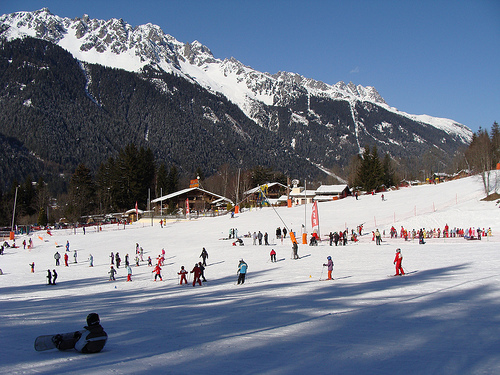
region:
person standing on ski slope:
[234, 261, 249, 282]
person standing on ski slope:
[324, 251, 343, 287]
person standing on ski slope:
[391, 243, 407, 285]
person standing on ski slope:
[264, 248, 278, 271]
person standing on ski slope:
[289, 238, 304, 259]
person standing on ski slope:
[56, 294, 100, 353]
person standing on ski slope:
[52, 249, 59, 268]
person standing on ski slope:
[70, 249, 82, 263]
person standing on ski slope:
[27, 237, 35, 244]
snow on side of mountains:
[87, 23, 244, 102]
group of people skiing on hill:
[33, 217, 484, 297]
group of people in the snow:
[78, 187, 433, 317]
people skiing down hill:
[107, 217, 453, 303]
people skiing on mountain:
[104, 202, 425, 309]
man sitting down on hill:
[23, 300, 113, 357]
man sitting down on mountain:
[28, 310, 113, 362]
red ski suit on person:
[390, 253, 405, 272]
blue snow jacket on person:
[238, 260, 250, 270]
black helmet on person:
[85, 312, 101, 327]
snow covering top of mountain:
[38, 8, 181, 80]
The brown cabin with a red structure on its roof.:
[151, 178, 234, 215]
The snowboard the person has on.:
[29, 335, 90, 350]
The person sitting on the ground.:
[36, 313, 111, 354]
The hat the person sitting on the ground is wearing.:
[87, 315, 104, 320]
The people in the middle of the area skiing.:
[27, 240, 433, 303]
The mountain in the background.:
[0, 4, 483, 192]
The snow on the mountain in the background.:
[2, 15, 479, 154]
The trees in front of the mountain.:
[7, 158, 277, 213]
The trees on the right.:
[348, 126, 498, 183]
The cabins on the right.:
[402, 162, 494, 189]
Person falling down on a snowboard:
[24, 308, 118, 360]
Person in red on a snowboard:
[390, 248, 407, 278]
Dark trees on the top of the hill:
[455, 115, 499, 177]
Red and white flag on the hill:
[305, 200, 325, 237]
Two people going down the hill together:
[42, 266, 57, 283]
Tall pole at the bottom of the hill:
[10, 177, 23, 234]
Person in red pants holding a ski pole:
[319, 252, 341, 285]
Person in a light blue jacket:
[233, 258, 250, 286]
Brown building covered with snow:
[144, 174, 243, 219]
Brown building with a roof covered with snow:
[311, 183, 348, 203]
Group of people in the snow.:
[312, 233, 424, 234]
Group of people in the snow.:
[220, 361, 301, 362]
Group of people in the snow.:
[113, 345, 304, 352]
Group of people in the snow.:
[33, 350, 164, 353]